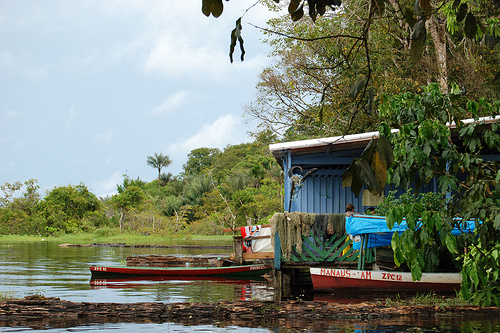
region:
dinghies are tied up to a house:
[83, 253, 498, 298]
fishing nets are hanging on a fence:
[264, 208, 345, 265]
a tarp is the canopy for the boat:
[310, 212, 479, 297]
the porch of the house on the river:
[287, 154, 495, 258]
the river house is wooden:
[278, 152, 493, 270]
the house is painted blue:
[273, 151, 495, 261]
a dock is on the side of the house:
[123, 221, 274, 264]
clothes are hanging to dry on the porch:
[230, 217, 275, 258]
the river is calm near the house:
[8, 238, 291, 309]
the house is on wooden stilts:
[268, 260, 308, 303]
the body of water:
[0, 240, 497, 330]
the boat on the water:
[307, 265, 462, 292]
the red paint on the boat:
[309, 264, 461, 293]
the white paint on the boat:
[309, 267, 463, 282]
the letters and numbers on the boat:
[318, 266, 401, 281]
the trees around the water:
[0, 0, 498, 310]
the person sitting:
[342, 202, 359, 214]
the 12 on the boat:
[395, 274, 402, 281]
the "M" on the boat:
[365, 272, 370, 279]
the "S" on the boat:
[345, 269, 351, 278]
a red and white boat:
[307, 265, 469, 296]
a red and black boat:
[87, 260, 272, 283]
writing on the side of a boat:
[318, 268, 407, 283]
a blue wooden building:
[267, 114, 498, 266]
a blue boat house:
[267, 112, 498, 270]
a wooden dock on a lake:
[125, 255, 239, 265]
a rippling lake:
[1, 245, 276, 296]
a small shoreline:
[4, 296, 498, 331]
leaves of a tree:
[373, 82, 498, 307]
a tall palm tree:
[147, 153, 172, 178]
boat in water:
[78, 245, 223, 275]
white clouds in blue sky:
[10, 20, 52, 68]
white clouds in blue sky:
[31, 79, 103, 133]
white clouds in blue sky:
[102, 33, 149, 80]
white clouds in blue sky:
[78, 109, 141, 148]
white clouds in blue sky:
[143, 39, 211, 111]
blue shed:
[262, 106, 387, 203]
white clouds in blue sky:
[15, 122, 63, 165]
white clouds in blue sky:
[90, 80, 159, 134]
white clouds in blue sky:
[90, 80, 131, 110]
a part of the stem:
[211, 2, 274, 77]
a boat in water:
[84, 238, 271, 306]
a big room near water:
[256, 115, 493, 315]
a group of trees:
[13, 164, 259, 226]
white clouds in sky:
[151, 95, 240, 165]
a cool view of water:
[8, 221, 255, 315]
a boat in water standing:
[89, 250, 282, 298]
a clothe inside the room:
[272, 185, 342, 252]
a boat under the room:
[306, 252, 458, 302]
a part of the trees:
[376, 89, 497, 302]